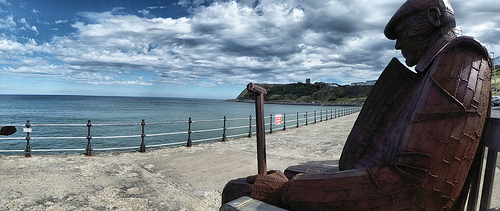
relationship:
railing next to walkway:
[1, 108, 364, 158] [1, 109, 499, 210]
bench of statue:
[219, 117, 499, 210] [219, 1, 499, 209]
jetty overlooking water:
[226, 79, 377, 107] [0, 95, 362, 153]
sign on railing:
[276, 113, 283, 126] [1, 108, 364, 158]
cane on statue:
[246, 81, 267, 174] [219, 1, 499, 209]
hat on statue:
[383, 0, 456, 40] [219, 1, 499, 209]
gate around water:
[0, 104, 363, 156] [0, 95, 362, 153]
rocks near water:
[223, 82, 375, 108] [0, 95, 362, 153]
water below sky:
[0, 95, 362, 153] [0, 0, 499, 99]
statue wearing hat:
[219, 1, 499, 209] [383, 1, 455, 40]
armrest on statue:
[220, 195, 293, 210] [219, 1, 499, 209]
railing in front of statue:
[1, 106, 365, 158] [219, 1, 499, 209]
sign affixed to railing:
[276, 113, 283, 126] [1, 106, 365, 158]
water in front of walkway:
[0, 95, 362, 153] [1, 109, 499, 210]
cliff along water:
[226, 78, 378, 108] [0, 95, 362, 153]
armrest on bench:
[220, 195, 293, 210] [219, 117, 499, 210]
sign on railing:
[276, 113, 283, 126] [1, 106, 365, 158]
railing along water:
[1, 106, 365, 158] [0, 95, 362, 153]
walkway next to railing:
[1, 109, 499, 210] [1, 106, 365, 158]